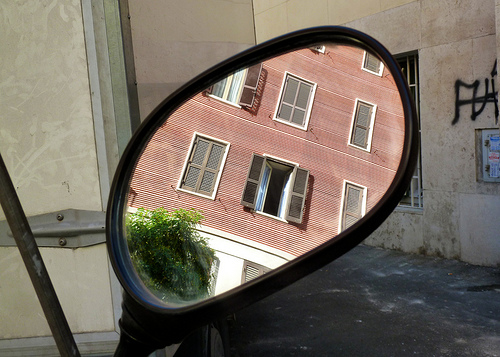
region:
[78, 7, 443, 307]
Side mirror of the vehicle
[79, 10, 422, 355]
Outer black color frame with glass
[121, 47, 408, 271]
A mirror reflecting the building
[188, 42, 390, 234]
A mirror relecting the windows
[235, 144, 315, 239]
One window was opened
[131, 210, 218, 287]
Mirror reflecting the tree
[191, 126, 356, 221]
Window is made up of wood and glass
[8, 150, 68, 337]
Steel rod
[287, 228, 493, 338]
Floor near the building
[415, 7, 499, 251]
Outer side wall of the building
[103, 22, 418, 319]
side view mirror with reflection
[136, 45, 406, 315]
reflection of brick building and tree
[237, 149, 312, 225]
open window in brick building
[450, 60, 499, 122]
black graffiti on wall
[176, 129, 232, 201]
window shutters closed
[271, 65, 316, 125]
window with shutters closed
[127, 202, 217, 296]
green tree in reflection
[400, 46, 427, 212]
partial window in white building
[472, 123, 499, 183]
sign on side of building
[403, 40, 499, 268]
white building beside road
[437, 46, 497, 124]
Graffiti sprayed on the wall.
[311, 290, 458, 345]
Pavement is on the ground.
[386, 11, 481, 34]
The wall is biege colored.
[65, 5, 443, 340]
A mirror is attached to a vehicle.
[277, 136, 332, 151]
The building is made out of brick.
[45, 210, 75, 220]
The screw is grey.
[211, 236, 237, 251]
Part of the building is white.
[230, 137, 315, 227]
A open window on the building.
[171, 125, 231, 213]
A closed window on the building.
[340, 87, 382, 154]
A skinny window on the building.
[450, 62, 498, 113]
Graffiti on the wall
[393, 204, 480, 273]
The wall is dirty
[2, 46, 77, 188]
A blank white wall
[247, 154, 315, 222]
An open window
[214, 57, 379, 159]
A row of windows on the building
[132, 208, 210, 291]
Reflection of a small green tree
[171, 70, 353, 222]
Reflection of a red brick building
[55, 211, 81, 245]
Two small screws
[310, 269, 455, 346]
Pavement by the building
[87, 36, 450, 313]
Side mirror of a vehicle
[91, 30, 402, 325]
black rear view mirror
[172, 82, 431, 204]
building has brick exterior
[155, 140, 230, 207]
white frame around window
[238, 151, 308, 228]
brown shutters on window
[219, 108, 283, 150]
bricks are red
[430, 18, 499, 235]
light brown wall with graffiti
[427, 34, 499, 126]
graffiti on wall is black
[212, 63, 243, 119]
white curtains in window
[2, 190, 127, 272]
grey hinge on door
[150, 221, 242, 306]
green tree under building